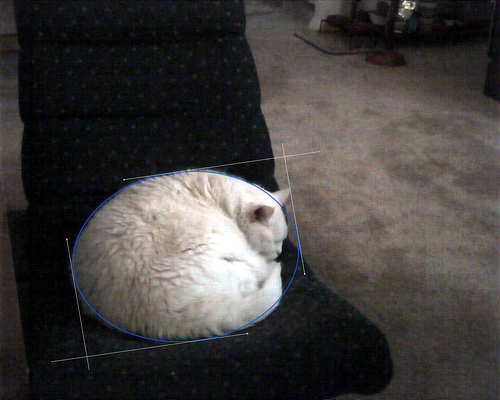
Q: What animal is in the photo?
A: Cat.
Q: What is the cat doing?
A: Sleeping.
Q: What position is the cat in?
A: Fetal position.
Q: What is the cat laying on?
A: Chair.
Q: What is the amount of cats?
A: One.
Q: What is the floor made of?
A: Carpet.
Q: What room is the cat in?
A: Living room.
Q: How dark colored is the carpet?
A: Light.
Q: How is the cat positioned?
A: Curled up.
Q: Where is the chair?
A: On the carpet.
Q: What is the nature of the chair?
A: Padded.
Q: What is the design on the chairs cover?
A: Polka dots.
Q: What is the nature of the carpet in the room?
A: Velvety.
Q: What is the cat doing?
A: Sleeping.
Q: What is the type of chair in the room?
A: Office chair.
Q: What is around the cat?
A: A blue circle.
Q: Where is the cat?
A: On the chair.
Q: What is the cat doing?
A: Curled up into a ball.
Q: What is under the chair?
A: Beige carpet.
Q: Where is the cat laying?
A: On a chair.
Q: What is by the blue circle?
A: Two white lines.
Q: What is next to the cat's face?
A: Two white lines.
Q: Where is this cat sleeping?
A: On a chair.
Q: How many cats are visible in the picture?
A: One.